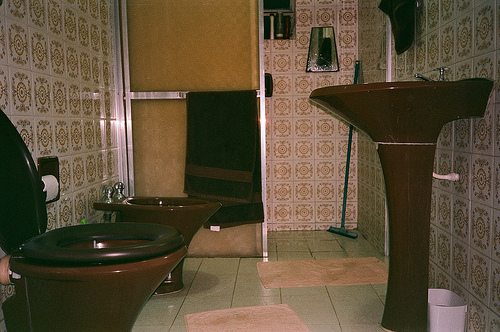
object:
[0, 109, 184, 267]
toilet seat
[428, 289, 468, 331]
trash can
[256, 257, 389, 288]
bath mat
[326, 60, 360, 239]
broom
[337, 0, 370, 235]
corner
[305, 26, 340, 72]
mirror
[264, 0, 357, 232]
wall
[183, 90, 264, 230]
towel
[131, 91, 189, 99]
rack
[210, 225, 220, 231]
tag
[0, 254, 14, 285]
pipe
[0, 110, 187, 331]
toilet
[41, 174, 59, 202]
toilet paper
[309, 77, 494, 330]
sink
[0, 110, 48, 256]
lid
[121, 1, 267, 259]
shower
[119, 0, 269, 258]
door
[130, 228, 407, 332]
floor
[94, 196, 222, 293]
bidet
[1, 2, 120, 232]
wall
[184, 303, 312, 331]
rug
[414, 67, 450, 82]
tap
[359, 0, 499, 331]
wall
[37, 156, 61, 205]
toilet paper holder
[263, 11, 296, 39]
toiletries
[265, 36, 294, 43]
holder